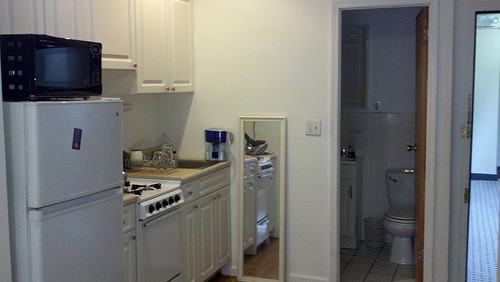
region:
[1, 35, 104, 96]
black microwave on top of the fridge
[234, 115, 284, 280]
full length mirror leaning against a wall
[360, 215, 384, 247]
bathroom waste basket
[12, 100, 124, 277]
white refrigerator with one magnet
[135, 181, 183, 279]
white stove with black knobs and a silver handle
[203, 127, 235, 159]
water pitcher sitting on the counter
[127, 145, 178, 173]
dish drying rack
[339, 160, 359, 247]
white bathroom cabinets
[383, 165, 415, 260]
white toilet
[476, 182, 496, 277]
tiled floor in the hallway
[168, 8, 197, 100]
Small white cabinet door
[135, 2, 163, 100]
Small white cabinet door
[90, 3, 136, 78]
Small white cabinet door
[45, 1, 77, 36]
Small white cabinet door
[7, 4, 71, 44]
Small white cabinet door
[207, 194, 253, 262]
Small white cabinet door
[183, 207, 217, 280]
Small white cabinet door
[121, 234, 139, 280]
Small white cabinet door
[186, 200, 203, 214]
Small knob on cabinet door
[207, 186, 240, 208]
Small knob on cabinet door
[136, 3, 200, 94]
the cabinets above the counter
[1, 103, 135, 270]
a white fridge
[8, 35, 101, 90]
a black microwave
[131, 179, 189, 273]
a white stove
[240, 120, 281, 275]
a mirror leaning against the wall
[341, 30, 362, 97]
the mirror above the sink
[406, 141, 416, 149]
a knob on the door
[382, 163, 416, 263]
a white toilet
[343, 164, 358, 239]
white cabinet under the sink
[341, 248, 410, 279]
tile in the bathroom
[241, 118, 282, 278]
a mirror on the wall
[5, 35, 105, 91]
a black microwave on the fridge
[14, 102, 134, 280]
a white refrigerator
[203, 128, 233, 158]
a water jug on the counter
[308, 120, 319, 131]
a light switch on the wall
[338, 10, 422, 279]
the door way to the bathroom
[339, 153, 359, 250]
a white cabinet in the bathroom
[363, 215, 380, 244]
a trash can next to the toilet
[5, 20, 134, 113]
black microwave on fridge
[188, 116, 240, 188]
jug on counter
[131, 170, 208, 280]
white stove in cabinets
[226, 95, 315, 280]
white floor mirror in kitchen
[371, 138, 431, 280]
white toilet in bathroom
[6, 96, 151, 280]
white fridge in kitchen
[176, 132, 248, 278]
white cabinet doors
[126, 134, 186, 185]
dish rack on counter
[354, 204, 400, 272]
white and silver garbage can in bathroom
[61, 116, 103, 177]
sticker on fridge